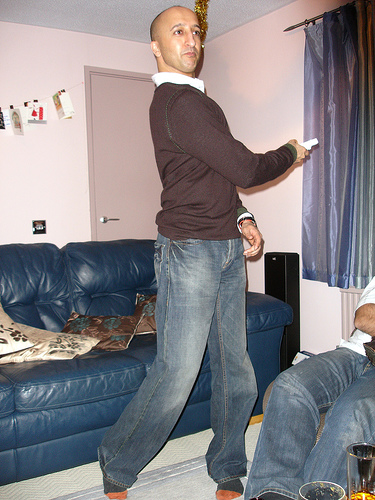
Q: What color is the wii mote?
A: White.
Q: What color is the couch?
A: Blue.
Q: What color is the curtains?
A: Purple.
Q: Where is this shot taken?
A: Living room.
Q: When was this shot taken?
A: Night time.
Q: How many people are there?
A: 2.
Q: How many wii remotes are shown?
A: 1.